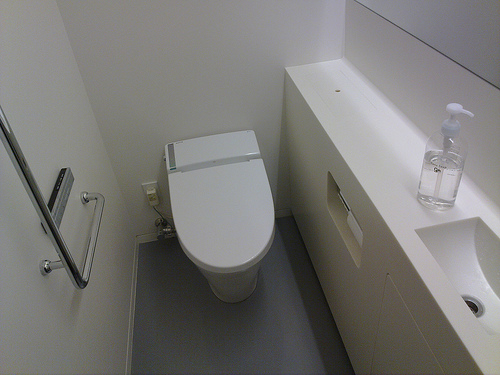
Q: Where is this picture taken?
A: In a bathroom.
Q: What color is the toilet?
A: White.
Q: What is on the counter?
A: Soap bottle.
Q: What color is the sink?
A: White.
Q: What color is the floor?
A: Gray.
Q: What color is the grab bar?
A: Chrome.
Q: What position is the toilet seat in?
A: Down.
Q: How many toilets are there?
A: 1.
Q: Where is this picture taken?
A: In a Restroom.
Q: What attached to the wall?
A: A toilet.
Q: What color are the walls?
A: White.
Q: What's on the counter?
A: Bottle with liquid.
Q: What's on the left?
A: Hand rail.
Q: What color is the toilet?
A: White.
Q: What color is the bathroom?
A: White.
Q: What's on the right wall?
A: A mirror.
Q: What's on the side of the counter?
A: Tissue.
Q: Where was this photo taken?
A: In a bathroom.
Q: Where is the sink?
A: On the right side.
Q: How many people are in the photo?
A: Zero.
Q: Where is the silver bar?
A: To the left of the toilet.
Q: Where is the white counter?
A: To the right of the toilet.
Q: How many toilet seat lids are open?
A: Zero.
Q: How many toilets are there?
A: One.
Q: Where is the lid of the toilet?
A: Down.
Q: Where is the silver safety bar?
A: Attached to the wall.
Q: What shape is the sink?
A: Rectangle.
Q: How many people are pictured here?
A: Zero.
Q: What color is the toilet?
A: White.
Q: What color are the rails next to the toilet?
A: Silver.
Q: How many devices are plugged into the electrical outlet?
A: One.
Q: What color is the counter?
A: White.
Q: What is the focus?
A: Bathroom toilet.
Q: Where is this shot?
A: Bathroom.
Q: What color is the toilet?
A: White.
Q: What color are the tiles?
A: White.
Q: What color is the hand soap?
A: Clear.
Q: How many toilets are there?
A: 1.